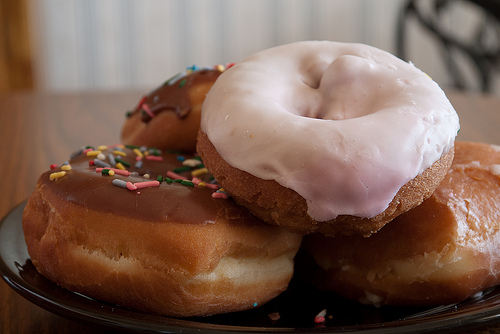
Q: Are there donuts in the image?
A: Yes, there is a donut.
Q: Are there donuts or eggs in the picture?
A: Yes, there is a donut.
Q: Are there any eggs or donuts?
A: Yes, there is a donut.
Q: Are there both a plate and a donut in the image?
A: Yes, there are both a donut and a plate.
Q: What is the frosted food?
A: The food is a donut.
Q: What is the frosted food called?
A: The food is a donut.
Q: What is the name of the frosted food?
A: The food is a donut.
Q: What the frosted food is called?
A: The food is a donut.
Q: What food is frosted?
A: The food is a donut.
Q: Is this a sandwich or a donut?
A: This is a donut.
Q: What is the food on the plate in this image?
A: The food is a donut.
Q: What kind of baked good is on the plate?
A: The food is a donut.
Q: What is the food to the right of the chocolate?
A: The food is a donut.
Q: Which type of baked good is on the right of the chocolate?
A: The food is a donut.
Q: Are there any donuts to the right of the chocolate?
A: Yes, there is a donut to the right of the chocolate.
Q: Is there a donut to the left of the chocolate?
A: No, the donut is to the right of the chocolate.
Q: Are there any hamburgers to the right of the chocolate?
A: No, there is a donut to the right of the chocolate.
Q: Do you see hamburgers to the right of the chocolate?
A: No, there is a donut to the right of the chocolate.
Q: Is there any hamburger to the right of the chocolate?
A: No, there is a donut to the right of the chocolate.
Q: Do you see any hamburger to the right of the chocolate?
A: No, there is a donut to the right of the chocolate.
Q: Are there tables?
A: Yes, there is a table.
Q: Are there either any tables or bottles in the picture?
A: Yes, there is a table.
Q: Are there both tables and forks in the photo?
A: No, there is a table but no forks.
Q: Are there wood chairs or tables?
A: Yes, there is a wood table.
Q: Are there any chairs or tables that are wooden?
A: Yes, the table is wooden.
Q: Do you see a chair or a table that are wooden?
A: Yes, the table is wooden.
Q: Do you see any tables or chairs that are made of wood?
A: Yes, the table is made of wood.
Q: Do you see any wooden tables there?
A: Yes, there is a wood table.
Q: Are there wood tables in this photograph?
A: Yes, there is a wood table.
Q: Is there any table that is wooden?
A: Yes, there is a table that is wooden.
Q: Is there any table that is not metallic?
A: Yes, there is a wooden table.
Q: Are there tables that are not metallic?
A: Yes, there is a wooden table.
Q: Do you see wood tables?
A: Yes, there is a table that is made of wood.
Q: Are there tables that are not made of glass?
A: Yes, there is a table that is made of wood.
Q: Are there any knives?
A: No, there are no knives.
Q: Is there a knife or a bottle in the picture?
A: No, there are no knives or bottles.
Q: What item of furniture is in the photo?
A: The piece of furniture is a table.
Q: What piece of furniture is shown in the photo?
A: The piece of furniture is a table.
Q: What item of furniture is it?
A: The piece of furniture is a table.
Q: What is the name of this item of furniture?
A: This is a table.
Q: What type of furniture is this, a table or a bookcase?
A: This is a table.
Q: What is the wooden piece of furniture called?
A: The piece of furniture is a table.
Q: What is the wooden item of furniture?
A: The piece of furniture is a table.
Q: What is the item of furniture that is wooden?
A: The piece of furniture is a table.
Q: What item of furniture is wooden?
A: The piece of furniture is a table.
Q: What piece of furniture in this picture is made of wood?
A: The piece of furniture is a table.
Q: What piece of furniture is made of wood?
A: The piece of furniture is a table.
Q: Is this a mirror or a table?
A: This is a table.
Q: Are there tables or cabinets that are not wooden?
A: No, there is a table but it is wooden.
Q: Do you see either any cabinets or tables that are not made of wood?
A: No, there is a table but it is made of wood.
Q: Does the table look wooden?
A: Yes, the table is wooden.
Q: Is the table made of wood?
A: Yes, the table is made of wood.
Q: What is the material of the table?
A: The table is made of wood.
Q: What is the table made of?
A: The table is made of wood.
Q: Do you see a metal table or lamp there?
A: No, there is a table but it is wooden.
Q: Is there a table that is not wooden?
A: No, there is a table but it is wooden.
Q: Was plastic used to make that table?
A: No, the table is made of wood.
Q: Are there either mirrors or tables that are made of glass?
A: No, there is a table but it is made of wood.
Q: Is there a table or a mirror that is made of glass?
A: No, there is a table but it is made of wood.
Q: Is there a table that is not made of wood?
A: No, there is a table but it is made of wood.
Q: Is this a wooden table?
A: Yes, this is a wooden table.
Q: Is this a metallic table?
A: No, this is a wooden table.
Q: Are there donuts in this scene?
A: Yes, there is a donut.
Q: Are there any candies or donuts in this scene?
A: Yes, there is a donut.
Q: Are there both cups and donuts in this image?
A: No, there is a donut but no cups.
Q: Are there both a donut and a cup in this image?
A: No, there is a donut but no cups.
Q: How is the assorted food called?
A: The food is a donut.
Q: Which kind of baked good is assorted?
A: The baked good is a donut.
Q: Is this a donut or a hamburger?
A: This is a donut.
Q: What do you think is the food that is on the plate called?
A: The food is a donut.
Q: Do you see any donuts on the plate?
A: Yes, there is a donut on the plate.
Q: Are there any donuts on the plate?
A: Yes, there is a donut on the plate.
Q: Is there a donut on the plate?
A: Yes, there is a donut on the plate.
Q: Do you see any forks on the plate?
A: No, there is a donut on the plate.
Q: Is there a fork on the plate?
A: No, there is a donut on the plate.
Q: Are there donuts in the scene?
A: Yes, there is a donut.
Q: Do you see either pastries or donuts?
A: Yes, there is a donut.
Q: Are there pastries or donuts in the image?
A: Yes, there is a donut.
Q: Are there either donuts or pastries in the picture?
A: Yes, there is a donut.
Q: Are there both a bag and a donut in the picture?
A: No, there is a donut but no bags.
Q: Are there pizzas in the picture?
A: No, there are no pizzas.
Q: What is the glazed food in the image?
A: The food is a donut.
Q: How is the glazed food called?
A: The food is a donut.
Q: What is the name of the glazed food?
A: The food is a donut.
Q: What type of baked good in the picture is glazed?
A: The baked good is a donut.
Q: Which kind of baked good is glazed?
A: The baked good is a donut.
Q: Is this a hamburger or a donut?
A: This is a donut.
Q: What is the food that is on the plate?
A: The food is a donut.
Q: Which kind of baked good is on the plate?
A: The food is a donut.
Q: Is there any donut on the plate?
A: Yes, there is a donut on the plate.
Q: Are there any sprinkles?
A: Yes, there are sprinkles.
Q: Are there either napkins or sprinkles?
A: Yes, there are sprinkles.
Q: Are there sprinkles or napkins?
A: Yes, there are sprinkles.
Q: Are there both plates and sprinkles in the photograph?
A: Yes, there are both sprinkles and a plate.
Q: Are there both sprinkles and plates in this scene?
A: Yes, there are both sprinkles and a plate.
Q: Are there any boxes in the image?
A: No, there are no boxes.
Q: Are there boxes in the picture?
A: No, there are no boxes.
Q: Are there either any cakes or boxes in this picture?
A: No, there are no boxes or cakes.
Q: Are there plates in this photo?
A: Yes, there is a plate.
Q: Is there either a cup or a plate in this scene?
A: Yes, there is a plate.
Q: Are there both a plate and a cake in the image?
A: No, there is a plate but no cakes.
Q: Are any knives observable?
A: No, there are no knives.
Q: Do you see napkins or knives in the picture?
A: No, there are no knives or napkins.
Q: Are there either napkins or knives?
A: No, there are no knives or napkins.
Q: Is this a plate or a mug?
A: This is a plate.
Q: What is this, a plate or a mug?
A: This is a plate.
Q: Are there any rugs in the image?
A: No, there are no rugs.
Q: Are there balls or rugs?
A: No, there are no rugs or balls.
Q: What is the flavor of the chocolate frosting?
A: That is a chocolate frosting.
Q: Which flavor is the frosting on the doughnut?
A: That is a chocolate frosting.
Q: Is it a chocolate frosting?
A: Yes, that is a chocolate frosting.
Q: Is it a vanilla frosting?
A: No, that is a chocolate frosting.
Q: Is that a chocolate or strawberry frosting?
A: That is a chocolate frosting.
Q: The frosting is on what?
A: The frosting is on the doughnut.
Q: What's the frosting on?
A: The frosting is on the doughnut.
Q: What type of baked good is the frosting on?
A: The frosting is on the doughnut.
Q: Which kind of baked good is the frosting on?
A: The frosting is on the doughnut.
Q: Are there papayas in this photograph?
A: No, there are no papayas.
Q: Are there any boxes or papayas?
A: No, there are no papayas or boxes.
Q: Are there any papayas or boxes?
A: No, there are no papayas or boxes.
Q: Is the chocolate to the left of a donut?
A: Yes, the chocolate is to the left of a donut.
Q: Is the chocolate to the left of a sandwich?
A: No, the chocolate is to the left of a donut.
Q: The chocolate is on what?
A: The chocolate is on the donut.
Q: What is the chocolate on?
A: The chocolate is on the donut.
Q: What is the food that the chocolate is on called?
A: The food is a donut.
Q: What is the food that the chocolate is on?
A: The food is a donut.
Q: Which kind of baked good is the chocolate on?
A: The chocolate is on the donut.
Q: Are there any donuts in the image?
A: Yes, there is a donut.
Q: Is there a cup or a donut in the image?
A: Yes, there is a donut.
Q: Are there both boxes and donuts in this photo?
A: No, there is a donut but no boxes.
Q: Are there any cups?
A: No, there are no cups.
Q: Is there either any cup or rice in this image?
A: No, there are no cups or rice.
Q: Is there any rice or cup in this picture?
A: No, there are no cups or rice.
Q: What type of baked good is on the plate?
A: The food is a donut.